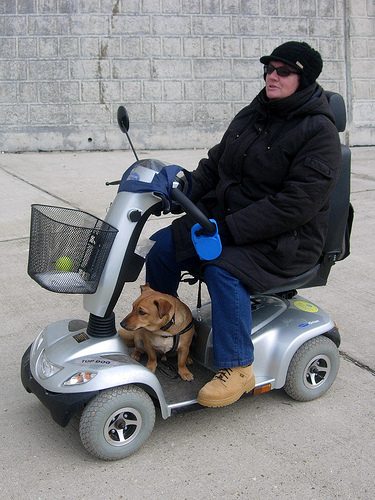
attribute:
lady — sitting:
[127, 42, 340, 430]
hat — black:
[263, 41, 322, 86]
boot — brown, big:
[194, 364, 255, 404]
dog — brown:
[122, 295, 206, 381]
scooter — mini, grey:
[14, 167, 344, 442]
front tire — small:
[74, 388, 163, 461]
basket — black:
[20, 203, 118, 295]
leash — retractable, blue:
[189, 220, 223, 268]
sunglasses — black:
[259, 61, 303, 82]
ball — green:
[57, 254, 77, 272]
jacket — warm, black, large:
[180, 86, 338, 286]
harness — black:
[151, 327, 198, 357]